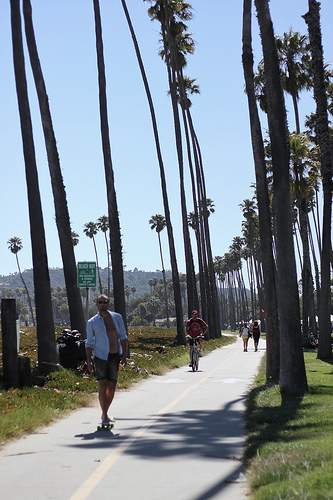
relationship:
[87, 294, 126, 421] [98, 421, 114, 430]
man on skateboard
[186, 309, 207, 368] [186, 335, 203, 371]
man riding bike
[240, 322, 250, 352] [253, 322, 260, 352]
woman walking with woman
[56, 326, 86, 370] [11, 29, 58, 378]
trash can by tree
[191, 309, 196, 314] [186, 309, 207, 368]
hat on man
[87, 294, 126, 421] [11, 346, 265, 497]
man skateboarding on road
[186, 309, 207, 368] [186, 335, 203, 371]
man on bike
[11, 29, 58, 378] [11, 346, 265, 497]
tree near road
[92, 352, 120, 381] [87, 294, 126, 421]
shorts on man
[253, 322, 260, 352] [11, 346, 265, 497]
woman on road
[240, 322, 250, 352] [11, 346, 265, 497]
woman on road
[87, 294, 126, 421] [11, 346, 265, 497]
man on road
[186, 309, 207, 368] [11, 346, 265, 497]
man on road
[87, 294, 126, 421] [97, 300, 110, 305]
man wearing sunglasses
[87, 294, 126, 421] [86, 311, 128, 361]
man wearing shirt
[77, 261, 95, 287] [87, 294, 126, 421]
sign behind man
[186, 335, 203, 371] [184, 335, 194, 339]
bike has handlebar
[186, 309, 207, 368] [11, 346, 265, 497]
man riding on road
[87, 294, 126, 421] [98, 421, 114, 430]
man riding skateboard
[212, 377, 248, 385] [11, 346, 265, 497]
arrow on road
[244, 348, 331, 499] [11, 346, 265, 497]
grass near road